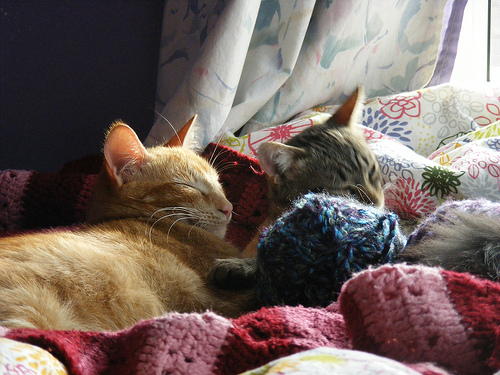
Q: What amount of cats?
A: Two.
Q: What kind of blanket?
A: Yarn.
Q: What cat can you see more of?
A: The orange cat.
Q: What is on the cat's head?
A: Ears.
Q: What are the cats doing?
A: Sleeping.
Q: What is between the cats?
A: A ball of yarn.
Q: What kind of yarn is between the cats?
A: A purple and blue ball of yarn.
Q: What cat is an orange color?
A: The left cat.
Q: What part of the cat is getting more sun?
A: The stomach.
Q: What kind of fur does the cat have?
A: Orange fur.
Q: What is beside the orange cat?
A: A grey cat.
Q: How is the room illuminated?
A: Sunlight.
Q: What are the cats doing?
A: Napping.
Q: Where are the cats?
A: Laying down.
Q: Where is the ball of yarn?
A: Between the cats.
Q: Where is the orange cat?
A: On the left.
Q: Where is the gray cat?
A: On the right.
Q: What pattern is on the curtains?
A: Flowers.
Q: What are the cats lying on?
A: A blanket.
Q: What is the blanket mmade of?
A: Yarn.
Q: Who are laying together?
A: Animals.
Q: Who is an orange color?
A: A cat.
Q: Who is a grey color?
A: A cat.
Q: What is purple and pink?
A: A blanket.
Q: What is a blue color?
A: A blanket.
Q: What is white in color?
A: A bed sheet.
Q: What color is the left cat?
A: Brown.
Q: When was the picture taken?
A: Daytime.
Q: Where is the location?
A: Bedroom.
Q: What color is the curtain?
A: White with flowers.